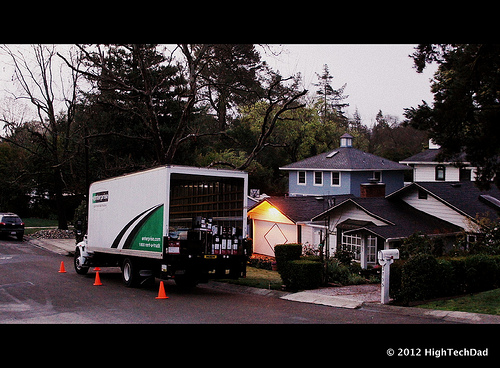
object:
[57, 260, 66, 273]
cone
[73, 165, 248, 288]
truck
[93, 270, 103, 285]
cone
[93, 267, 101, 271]
cone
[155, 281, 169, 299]
cone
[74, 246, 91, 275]
tire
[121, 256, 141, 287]
tire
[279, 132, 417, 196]
house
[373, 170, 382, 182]
window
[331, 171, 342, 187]
window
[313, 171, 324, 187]
window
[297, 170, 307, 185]
window